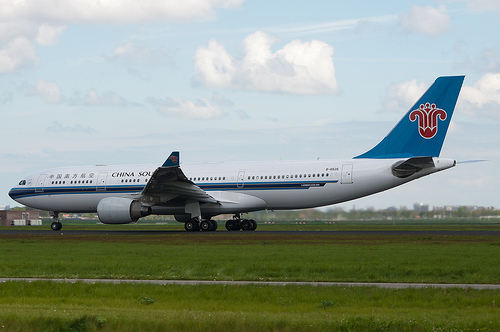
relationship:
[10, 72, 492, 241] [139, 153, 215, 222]
airplane with wing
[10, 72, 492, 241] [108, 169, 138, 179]
airplane from china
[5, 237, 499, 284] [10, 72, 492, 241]
grassy area left of airplane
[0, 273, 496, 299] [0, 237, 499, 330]
sidewalk between grass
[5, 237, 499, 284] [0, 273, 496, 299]
grassy area left of sidewalk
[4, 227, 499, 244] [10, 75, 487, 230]
runway for airplane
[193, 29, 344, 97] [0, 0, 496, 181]
cloud in sky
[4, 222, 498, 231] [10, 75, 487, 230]
grassy area right of airplane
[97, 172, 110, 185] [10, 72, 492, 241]
door of airplane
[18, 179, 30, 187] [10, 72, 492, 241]
windshield of airplane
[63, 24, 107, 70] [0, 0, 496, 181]
blue of sky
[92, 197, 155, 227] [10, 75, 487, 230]
engine of airplane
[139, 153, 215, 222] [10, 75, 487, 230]
wing of airplane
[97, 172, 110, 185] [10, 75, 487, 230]
door of airplane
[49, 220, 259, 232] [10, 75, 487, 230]
wheels of airplane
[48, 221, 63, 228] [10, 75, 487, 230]
wheel of airplane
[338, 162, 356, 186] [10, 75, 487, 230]
door of airplane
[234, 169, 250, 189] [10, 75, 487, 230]
door of airplane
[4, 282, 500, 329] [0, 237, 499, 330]
green of grass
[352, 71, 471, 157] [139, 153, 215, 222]
tail of wing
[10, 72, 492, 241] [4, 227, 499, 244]
jet on runway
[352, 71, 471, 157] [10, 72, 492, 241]
tail on jet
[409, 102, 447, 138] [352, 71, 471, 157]
design on tail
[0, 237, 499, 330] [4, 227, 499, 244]
grass surrounds runway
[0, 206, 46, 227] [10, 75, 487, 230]
buildings near airplane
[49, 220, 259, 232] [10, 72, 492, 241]
wheels on jet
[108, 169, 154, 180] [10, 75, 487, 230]
writing on airplane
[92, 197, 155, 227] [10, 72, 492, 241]
engine on jet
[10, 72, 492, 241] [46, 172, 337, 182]
jet has windows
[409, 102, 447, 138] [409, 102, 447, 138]
design white design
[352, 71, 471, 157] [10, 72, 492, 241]
tail of airplane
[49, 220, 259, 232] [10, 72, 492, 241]
wheels of airplane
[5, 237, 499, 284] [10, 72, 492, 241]
grassy area around airplane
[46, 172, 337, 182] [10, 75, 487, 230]
windows of airplane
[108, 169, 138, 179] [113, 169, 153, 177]
china sol title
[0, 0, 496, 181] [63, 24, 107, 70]
sky baby blue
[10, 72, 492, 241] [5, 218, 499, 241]
airplane on tarmac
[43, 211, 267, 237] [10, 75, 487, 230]
gear on airplane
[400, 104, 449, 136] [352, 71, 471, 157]
design on tail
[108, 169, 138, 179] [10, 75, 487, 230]
china on airplane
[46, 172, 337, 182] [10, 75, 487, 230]
windows for airplane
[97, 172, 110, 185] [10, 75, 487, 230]
door near airplane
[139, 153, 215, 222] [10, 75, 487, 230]
wing on airplane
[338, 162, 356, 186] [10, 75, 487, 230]
door on airplane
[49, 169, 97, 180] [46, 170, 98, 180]
chinese black characters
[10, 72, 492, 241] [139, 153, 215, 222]
airplane has wing